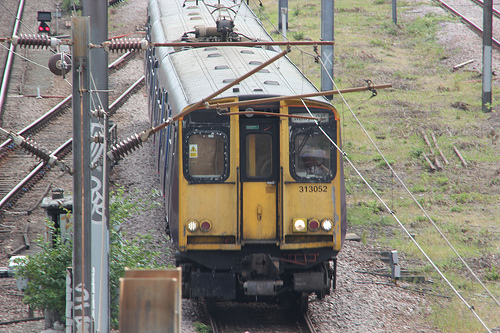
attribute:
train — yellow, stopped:
[151, 1, 343, 325]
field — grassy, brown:
[340, 5, 499, 327]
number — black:
[298, 186, 329, 193]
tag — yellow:
[191, 144, 196, 159]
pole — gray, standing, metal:
[83, 1, 108, 332]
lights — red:
[40, 25, 51, 34]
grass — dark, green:
[350, 176, 498, 333]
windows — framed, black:
[184, 135, 334, 180]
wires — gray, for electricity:
[283, 53, 499, 328]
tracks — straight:
[196, 299, 316, 331]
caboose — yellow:
[161, 56, 338, 248]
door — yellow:
[240, 133, 277, 236]